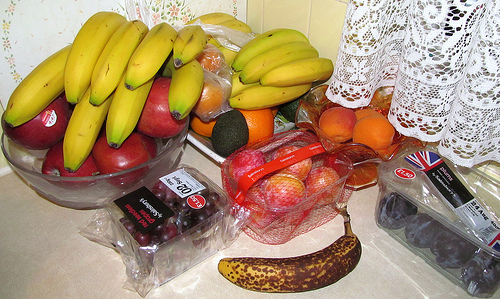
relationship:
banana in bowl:
[265, 58, 333, 86] [4, 144, 202, 211]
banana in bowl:
[228, 82, 313, 110] [4, 144, 202, 211]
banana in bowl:
[65, 15, 112, 103] [4, 144, 202, 211]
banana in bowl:
[8, 45, 65, 128] [4, 144, 202, 211]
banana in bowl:
[66, 108, 100, 173] [4, 144, 202, 211]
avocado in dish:
[211, 110, 249, 158] [185, 111, 295, 163]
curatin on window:
[337, 10, 493, 157] [424, 1, 499, 194]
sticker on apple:
[34, 109, 63, 137] [0, 93, 69, 142]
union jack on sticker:
[360, 129, 486, 230] [405, 150, 498, 248]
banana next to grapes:
[218, 205, 363, 293] [85, 161, 252, 293]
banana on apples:
[2, 44, 72, 128] [20, 85, 181, 174]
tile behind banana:
[243, 0, 310, 41] [258, 55, 337, 91]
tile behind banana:
[243, 0, 310, 41] [235, 42, 314, 84]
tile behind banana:
[243, 0, 310, 41] [231, 28, 309, 72]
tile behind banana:
[243, 0, 310, 41] [228, 79, 311, 113]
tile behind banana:
[307, 0, 349, 45] [258, 55, 337, 91]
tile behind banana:
[307, 0, 349, 45] [235, 42, 314, 84]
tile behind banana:
[307, 0, 349, 45] [231, 28, 309, 72]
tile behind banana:
[307, 0, 349, 45] [228, 79, 311, 113]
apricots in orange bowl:
[322, 102, 396, 147] [318, 106, 395, 199]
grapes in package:
[89, 186, 216, 260] [76, 163, 250, 296]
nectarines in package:
[203, 122, 355, 245] [221, 127, 355, 245]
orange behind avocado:
[193, 108, 275, 148] [213, 107, 249, 158]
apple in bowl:
[0, 98, 71, 149] [5, 102, 196, 211]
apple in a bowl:
[0, 98, 71, 149] [0, 124, 195, 209]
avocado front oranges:
[212, 110, 248, 154] [240, 108, 273, 139]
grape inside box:
[154, 218, 175, 243] [103, 164, 233, 289]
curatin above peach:
[324, 0, 499, 168] [356, 112, 404, 160]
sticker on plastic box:
[186, 192, 204, 208] [77, 186, 218, 285]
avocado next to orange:
[211, 110, 249, 158] [237, 107, 270, 139]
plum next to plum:
[377, 189, 416, 231] [403, 215, 443, 249]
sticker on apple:
[41, 110, 57, 128] [16, 106, 78, 148]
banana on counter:
[218, 205, 363, 293] [25, 175, 481, 272]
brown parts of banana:
[275, 258, 358, 275] [210, 223, 394, 297]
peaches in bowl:
[374, 89, 434, 148] [336, 145, 375, 186]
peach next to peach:
[318, 108, 355, 140] [354, 115, 395, 151]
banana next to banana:
[265, 58, 333, 86] [236, 38, 319, 83]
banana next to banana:
[232, 24, 312, 67] [228, 82, 315, 107]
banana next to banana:
[228, 82, 315, 107] [170, 22, 210, 72]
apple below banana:
[95, 133, 155, 186] [166, 56, 203, 120]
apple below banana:
[42, 139, 94, 184] [105, 77, 150, 145]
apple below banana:
[3, 92, 73, 143] [6, 45, 72, 130]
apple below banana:
[141, 77, 184, 147] [166, 56, 203, 120]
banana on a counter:
[217, 202, 362, 293] [1, 170, 470, 297]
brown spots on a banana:
[225, 255, 232, 262] [217, 227, 377, 292]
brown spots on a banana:
[230, 262, 239, 274] [217, 227, 377, 292]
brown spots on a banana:
[225, 270, 232, 279] [217, 227, 377, 292]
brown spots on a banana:
[226, 273, 235, 283] [217, 227, 377, 292]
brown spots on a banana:
[261, 264, 271, 271] [217, 227, 377, 292]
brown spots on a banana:
[226, 257, 229, 264] [216, 217, 371, 291]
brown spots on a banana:
[225, 260, 230, 267] [216, 217, 371, 291]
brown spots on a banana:
[241, 262, 250, 272] [216, 217, 371, 291]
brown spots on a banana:
[223, 271, 232, 274] [216, 217, 371, 291]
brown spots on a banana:
[228, 270, 237, 279] [216, 217, 371, 291]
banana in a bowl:
[231, 28, 311, 72] [8, 155, 151, 207]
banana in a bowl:
[2, 44, 72, 128] [8, 155, 151, 207]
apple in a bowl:
[136, 75, 188, 139] [8, 155, 151, 207]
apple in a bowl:
[91, 128, 157, 190] [8, 155, 151, 207]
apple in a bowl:
[42, 140, 99, 191] [8, 155, 151, 207]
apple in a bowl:
[0, 98, 71, 149] [8, 155, 151, 207]